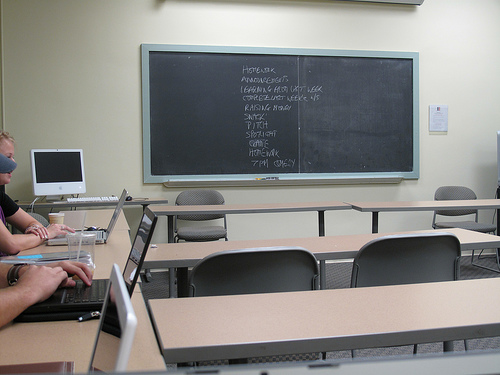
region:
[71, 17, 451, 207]
a black chalkboard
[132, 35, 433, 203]
a black chalkboard with writing on it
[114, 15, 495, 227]
a blackchalk board framed in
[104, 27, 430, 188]
a black chalkboard on the wall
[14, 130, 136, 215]
a white computer on the desk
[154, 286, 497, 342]
a long table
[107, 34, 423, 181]
a chalkboard framed in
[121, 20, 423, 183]
a chalkboard with white lettering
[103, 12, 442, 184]
a chalkboard on the wall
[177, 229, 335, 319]
a chair underneath the table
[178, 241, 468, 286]
Chairs by a table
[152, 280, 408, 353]
Table in a classroom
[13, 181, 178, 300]
Laptop on a desk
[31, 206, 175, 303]
Black computer on a desk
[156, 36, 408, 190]
Chalkboard in front of a room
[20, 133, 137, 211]
Computer on a table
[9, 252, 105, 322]
Hands on a computer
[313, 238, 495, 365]
Carpet on a floor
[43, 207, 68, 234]
Cup on a table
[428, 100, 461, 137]
Sign on a wall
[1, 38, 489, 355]
classroom with chalkboard and people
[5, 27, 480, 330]
classroom with chalkboard and people on laptops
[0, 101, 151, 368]
people in laptops in classroom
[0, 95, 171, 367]
people sitting with laptop computers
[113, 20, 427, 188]
large chalkboard in classroom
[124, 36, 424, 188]
full size chalkboard in room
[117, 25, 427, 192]
blackboard on wall in room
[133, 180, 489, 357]
empty chairs and tables in room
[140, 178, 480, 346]
empty tables and chairs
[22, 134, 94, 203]
large computer monitor next to wall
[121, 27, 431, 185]
a chalk board on the wall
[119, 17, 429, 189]
a black chalk board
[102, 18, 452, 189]
a chalkboard with writing on it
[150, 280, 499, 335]
a long table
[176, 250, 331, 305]
a chair underneath a table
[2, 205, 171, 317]
someone on a laptop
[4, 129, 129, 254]
someone looking at a laptop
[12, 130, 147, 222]
a desktop on a desk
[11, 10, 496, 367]
a classroom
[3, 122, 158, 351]
two people are in the classroom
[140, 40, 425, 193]
a chalkboard is on the wall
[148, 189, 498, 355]
metal chairs are at the tables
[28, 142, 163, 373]
four computers are in the room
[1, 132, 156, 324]
the people are using laptops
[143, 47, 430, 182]
white writing is on the chalkboard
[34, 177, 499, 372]
matching tables are lined up in the room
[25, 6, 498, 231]
the wall is light beige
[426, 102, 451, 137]
a white paper is hanging on the wall